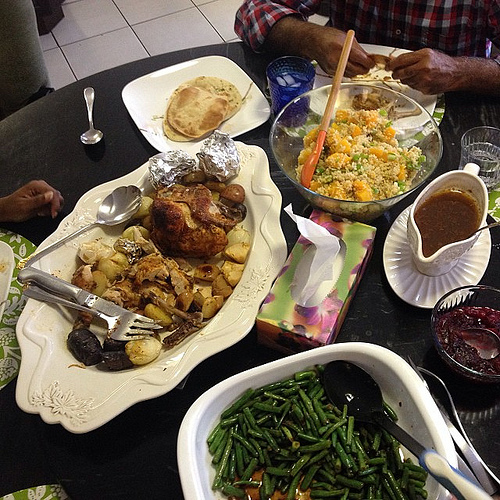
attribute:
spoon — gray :
[92, 169, 145, 229]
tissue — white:
[254, 205, 376, 351]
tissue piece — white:
[284, 201, 341, 308]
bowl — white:
[268, 61, 465, 238]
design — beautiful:
[29, 381, 95, 427]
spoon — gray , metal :
[78, 81, 103, 147]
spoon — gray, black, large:
[309, 355, 494, 498]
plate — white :
[97, 40, 268, 102]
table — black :
[2, 35, 499, 497]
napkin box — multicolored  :
[341, 227, 366, 292]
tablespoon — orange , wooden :
[298, 30, 355, 190]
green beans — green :
[205, 365, 432, 497]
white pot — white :
[172, 335, 459, 499]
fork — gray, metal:
[113, 318, 148, 337]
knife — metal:
[99, 301, 119, 311]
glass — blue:
[263, 57, 321, 114]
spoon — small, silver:
[81, 87, 104, 145]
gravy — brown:
[415, 191, 475, 254]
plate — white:
[10, 138, 289, 434]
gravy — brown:
[409, 189, 477, 257]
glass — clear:
[455, 127, 484, 175]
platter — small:
[120, 56, 269, 155]